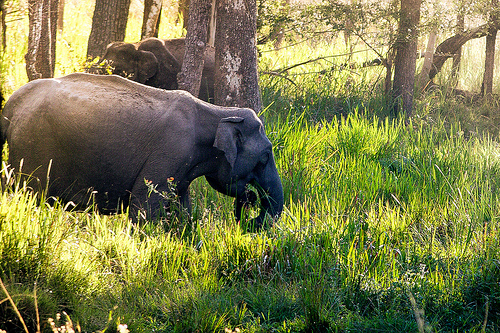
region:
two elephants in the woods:
[16, 3, 329, 296]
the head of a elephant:
[203, 90, 291, 252]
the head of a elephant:
[91, 40, 158, 85]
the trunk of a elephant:
[235, 188, 292, 234]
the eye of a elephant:
[252, 150, 267, 172]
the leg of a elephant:
[122, 160, 177, 227]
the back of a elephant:
[61, 65, 186, 115]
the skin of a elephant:
[40, 97, 160, 183]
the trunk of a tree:
[211, 39, 262, 107]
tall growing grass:
[316, 114, 463, 259]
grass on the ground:
[114, 236, 216, 304]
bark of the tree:
[395, 5, 417, 105]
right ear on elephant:
[207, 116, 242, 172]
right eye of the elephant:
[254, 146, 269, 168]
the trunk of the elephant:
[238, 170, 286, 230]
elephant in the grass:
[4, 70, 286, 244]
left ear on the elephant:
[131, 52, 164, 80]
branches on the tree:
[331, 5, 397, 53]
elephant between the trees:
[100, 35, 190, 81]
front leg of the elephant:
[127, 181, 166, 221]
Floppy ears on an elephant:
[209, 115, 246, 165]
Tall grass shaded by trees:
[16, 129, 489, 326]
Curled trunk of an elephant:
[233, 180, 287, 232]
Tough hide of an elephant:
[30, 90, 187, 206]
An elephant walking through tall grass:
[2, 74, 282, 229]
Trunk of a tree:
[215, 1, 263, 113]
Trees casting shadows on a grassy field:
[28, 3, 464, 115]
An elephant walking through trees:
[98, 34, 192, 86]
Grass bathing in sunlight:
[5, 189, 153, 293]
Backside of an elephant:
[0, 72, 72, 190]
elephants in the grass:
[12, 25, 325, 250]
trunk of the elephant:
[230, 185, 279, 231]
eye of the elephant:
[246, 133, 272, 163]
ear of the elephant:
[206, 110, 245, 165]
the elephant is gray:
[38, 96, 149, 178]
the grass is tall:
[212, 260, 327, 314]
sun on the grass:
[15, 233, 140, 290]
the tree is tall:
[375, 0, 420, 125]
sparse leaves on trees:
[242, 1, 370, 48]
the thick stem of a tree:
[219, 8, 259, 98]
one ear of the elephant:
[216, 115, 243, 163]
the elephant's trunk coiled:
[239, 180, 281, 230]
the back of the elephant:
[66, 66, 172, 99]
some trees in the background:
[186, 8, 496, 111]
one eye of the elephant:
[254, 148, 269, 168]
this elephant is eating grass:
[6, 74, 286, 249]